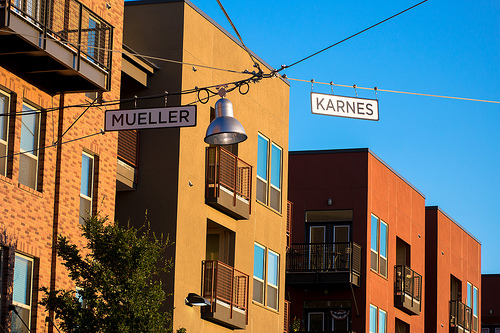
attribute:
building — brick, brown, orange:
[0, 1, 290, 332]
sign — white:
[101, 104, 198, 131]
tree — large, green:
[39, 210, 188, 333]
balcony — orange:
[201, 257, 250, 331]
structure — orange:
[287, 148, 483, 332]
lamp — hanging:
[203, 97, 250, 148]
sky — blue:
[189, 2, 499, 277]